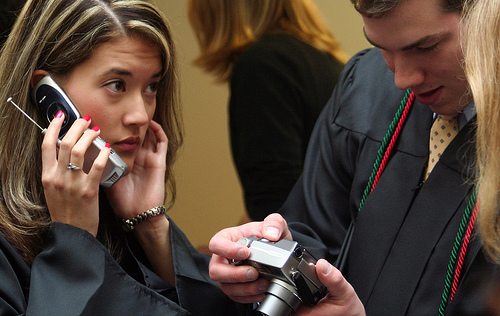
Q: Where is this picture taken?
A: Graduation.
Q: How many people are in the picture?
A: Four.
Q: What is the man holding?
A: Camera.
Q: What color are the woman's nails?
A: Red.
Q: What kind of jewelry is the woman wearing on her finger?
A: Ring.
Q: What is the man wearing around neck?
A: Cords.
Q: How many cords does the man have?
A: Two.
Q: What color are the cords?
A: Red and green.